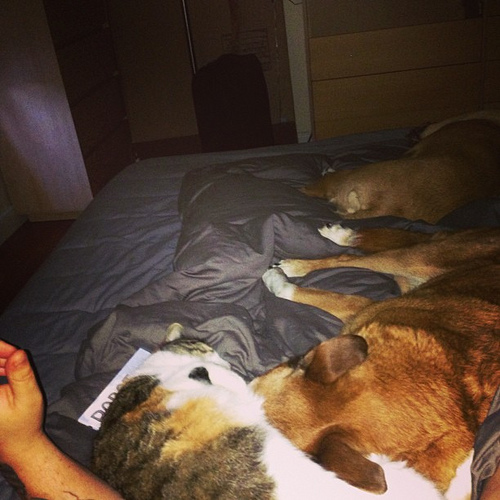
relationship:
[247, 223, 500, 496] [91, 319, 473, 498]
animal by cat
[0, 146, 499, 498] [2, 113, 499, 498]
blanket on bed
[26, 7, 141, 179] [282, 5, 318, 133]
panels on wall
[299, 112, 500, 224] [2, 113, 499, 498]
animal on bed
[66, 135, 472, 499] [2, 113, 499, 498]
comforter on bed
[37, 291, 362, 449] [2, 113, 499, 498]
pillow on bed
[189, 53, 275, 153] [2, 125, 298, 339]
luggage on floor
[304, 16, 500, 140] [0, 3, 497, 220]
panel on wall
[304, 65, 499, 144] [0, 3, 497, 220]
panel on wall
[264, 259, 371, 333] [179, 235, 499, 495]
leg of dog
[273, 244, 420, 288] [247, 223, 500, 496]
leg of animal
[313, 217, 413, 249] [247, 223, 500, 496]
leg of animal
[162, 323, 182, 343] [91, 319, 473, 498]
ear of cat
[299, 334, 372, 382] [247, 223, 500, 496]
ear of animal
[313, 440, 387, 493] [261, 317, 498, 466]
ear of dog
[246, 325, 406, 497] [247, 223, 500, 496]
head of animal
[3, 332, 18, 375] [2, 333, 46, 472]
finger of hand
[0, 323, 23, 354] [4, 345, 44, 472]
finger of hand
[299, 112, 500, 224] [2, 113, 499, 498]
animal lying on bed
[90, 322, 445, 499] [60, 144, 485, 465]
animal laying on bed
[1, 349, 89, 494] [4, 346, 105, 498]
arm of person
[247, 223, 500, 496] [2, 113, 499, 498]
animal laying on bed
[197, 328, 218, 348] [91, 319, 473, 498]
ear of cat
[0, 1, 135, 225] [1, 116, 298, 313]
shelf on a floor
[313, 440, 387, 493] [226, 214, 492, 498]
ear of a dog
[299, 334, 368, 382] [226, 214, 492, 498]
ear of a dog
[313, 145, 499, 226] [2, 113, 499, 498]
animal on bed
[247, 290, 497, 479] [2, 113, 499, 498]
animal on bed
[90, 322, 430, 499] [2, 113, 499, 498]
animal on bed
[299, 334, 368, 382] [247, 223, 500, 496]
ear of animal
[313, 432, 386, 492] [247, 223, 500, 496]
ear of animal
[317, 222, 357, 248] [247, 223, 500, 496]
paw of animal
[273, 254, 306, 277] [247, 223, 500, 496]
paw of animal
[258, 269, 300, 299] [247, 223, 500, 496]
paw of animal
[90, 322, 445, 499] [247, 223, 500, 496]
animal sleeping by animal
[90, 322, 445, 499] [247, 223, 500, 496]
animal cuddling with animal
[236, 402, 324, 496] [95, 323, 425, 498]
belly of cat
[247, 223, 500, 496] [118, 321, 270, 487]
animal sleeping with cat